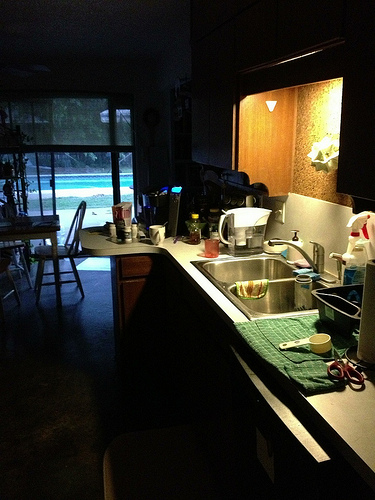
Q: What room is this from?
A: Kitchen.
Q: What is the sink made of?
A: Stainless steel.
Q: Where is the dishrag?
A: In the sink.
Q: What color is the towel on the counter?
A: Green.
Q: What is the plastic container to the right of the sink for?
A: Drying dishes.